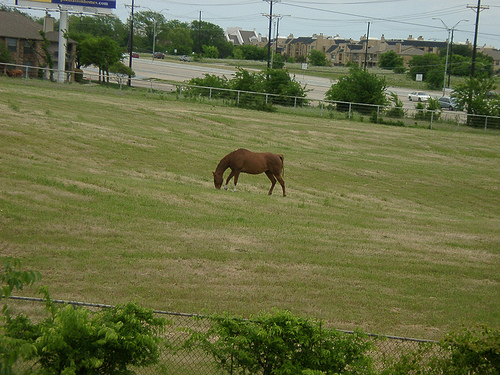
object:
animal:
[210, 148, 286, 196]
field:
[0, 73, 499, 375]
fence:
[0, 62, 499, 134]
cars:
[406, 90, 435, 102]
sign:
[13, 0, 117, 19]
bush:
[321, 65, 389, 115]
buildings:
[0, 9, 78, 84]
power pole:
[266, 1, 272, 82]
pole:
[58, 10, 67, 84]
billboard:
[13, 0, 118, 9]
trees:
[320, 57, 392, 113]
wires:
[140, 0, 271, 9]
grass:
[435, 281, 497, 325]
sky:
[0, 0, 500, 55]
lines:
[160, 0, 272, 7]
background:
[0, 0, 500, 375]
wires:
[151, 84, 179, 88]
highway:
[79, 52, 494, 124]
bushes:
[278, 75, 312, 107]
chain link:
[122, 81, 152, 86]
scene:
[1, 2, 498, 372]